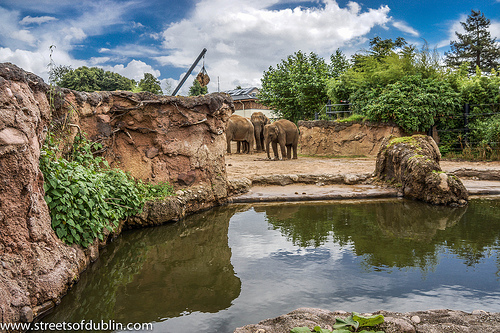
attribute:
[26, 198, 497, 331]
water — green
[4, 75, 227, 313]
cliff — brown 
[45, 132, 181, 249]
vine — Green 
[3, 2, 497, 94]
sky — blue 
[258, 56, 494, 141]
foliage — Dense 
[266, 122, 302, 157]
elephant — brown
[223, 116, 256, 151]
elephant — brown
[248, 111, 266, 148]
elephant — brown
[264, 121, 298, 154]
elephant — brown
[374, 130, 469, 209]
boulder — large 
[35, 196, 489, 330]
pool — large 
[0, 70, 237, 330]
cliff — brown 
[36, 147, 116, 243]
bush vine — green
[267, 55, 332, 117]
tree — large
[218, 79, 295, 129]
structure — large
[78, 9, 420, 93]
sky — blue, cloudy